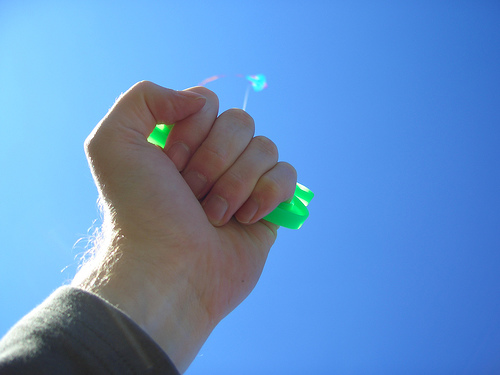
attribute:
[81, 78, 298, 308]
hand — in the air, closed, making a fist, raised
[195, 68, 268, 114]
kite — high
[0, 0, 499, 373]
sky — clear, beautiful, blue, bright, brightened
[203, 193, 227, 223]
fingernail — pink, short, clear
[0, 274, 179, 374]
shirt sleeve — grey, dark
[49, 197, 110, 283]
hairs — glowing in sun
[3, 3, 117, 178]
circle — green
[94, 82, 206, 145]
thumb — bent, resting, folded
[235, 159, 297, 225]
pinky finger — the shortest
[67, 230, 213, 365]
wrist — hairy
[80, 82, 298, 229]
fingers — folded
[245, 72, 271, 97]
part — folded